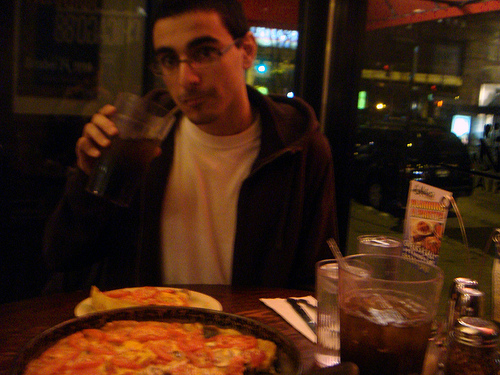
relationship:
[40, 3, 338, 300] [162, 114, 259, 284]
man wearing shirt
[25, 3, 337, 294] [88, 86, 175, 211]
man holding drink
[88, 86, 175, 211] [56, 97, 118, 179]
drink in hand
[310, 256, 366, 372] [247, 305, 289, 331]
glass on table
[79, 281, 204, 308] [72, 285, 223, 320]
sliced pizza on plate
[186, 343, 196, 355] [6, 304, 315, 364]
tomatoes on pizza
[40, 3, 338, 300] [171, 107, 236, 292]
man wearing shirt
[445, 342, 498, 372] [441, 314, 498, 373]
red pepper flakes on in jar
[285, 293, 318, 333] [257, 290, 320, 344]
silverware on napkin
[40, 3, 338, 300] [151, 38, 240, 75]
man wearing glasses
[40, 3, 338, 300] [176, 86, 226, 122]
man with facial hair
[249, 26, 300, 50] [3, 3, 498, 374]
window of restaurant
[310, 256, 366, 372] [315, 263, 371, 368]
glass of water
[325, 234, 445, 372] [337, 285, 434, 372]
glass of soda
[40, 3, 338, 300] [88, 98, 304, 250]
man wears shirt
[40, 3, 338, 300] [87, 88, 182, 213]
man holds cup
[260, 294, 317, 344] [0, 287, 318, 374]
napkin on table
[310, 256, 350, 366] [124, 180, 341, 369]
glass in front of man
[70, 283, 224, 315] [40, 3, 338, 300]
plate of pizza front of man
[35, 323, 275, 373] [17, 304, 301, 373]
pizza on a tray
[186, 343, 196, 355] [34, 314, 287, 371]
tomatoes on a pizza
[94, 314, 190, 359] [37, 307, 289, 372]
tomatoes on a pizza